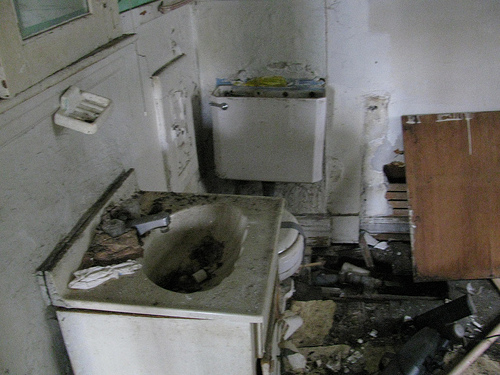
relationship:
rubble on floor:
[313, 286, 448, 366] [285, 240, 500, 375]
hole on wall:
[360, 154, 410, 234] [191, 0, 498, 235]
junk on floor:
[284, 227, 499, 372] [251, 193, 490, 373]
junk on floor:
[284, 227, 500, 375] [253, 142, 450, 368]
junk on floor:
[284, 227, 500, 375] [275, 160, 497, 367]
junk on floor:
[284, 227, 500, 375] [266, 170, 486, 371]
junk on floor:
[284, 227, 500, 375] [280, 227, 490, 373]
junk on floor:
[284, 227, 500, 375] [306, 239, 488, 373]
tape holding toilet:
[283, 220, 310, 241] [277, 210, 305, 281]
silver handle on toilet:
[210, 100, 230, 111] [211, 85, 324, 300]